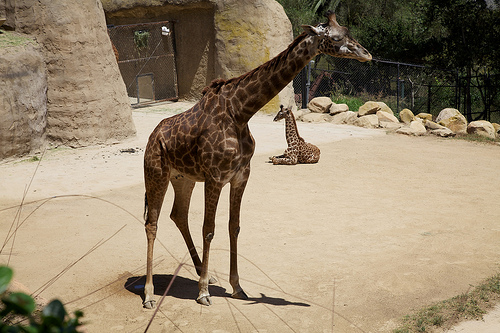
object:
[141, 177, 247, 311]
legs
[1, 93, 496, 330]
ground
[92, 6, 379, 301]
giraffe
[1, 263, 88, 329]
leaves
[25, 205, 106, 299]
foreground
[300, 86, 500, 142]
rock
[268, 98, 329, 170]
giraffe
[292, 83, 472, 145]
pile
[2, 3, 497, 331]
zoo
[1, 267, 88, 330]
plants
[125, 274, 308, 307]
shadow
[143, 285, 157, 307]
feet